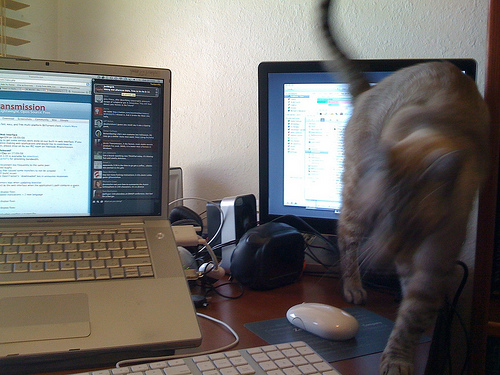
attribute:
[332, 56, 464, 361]
cat — gray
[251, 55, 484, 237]
flat screen — black, rectangular, computer monitor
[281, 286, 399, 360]
mouse — white, wireless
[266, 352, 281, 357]
key — white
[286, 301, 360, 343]
computer mouse — white, plastic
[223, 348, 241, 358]
key — white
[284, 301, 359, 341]
mouse — white, wireless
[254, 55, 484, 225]
computer monitor — additional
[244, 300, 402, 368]
mouse pad — Black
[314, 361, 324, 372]
key — white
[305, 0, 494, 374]
cat — brown, black, gray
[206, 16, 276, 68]
wall — white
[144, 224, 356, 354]
desk — wooden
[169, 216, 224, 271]
cable — white, plastic, connector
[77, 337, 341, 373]
keyboard — external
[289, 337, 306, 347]
key — white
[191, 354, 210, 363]
key — white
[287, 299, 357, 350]
mouse pad — square, flat, black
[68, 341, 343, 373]
keyboard — flat white, gray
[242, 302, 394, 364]
mousepad — black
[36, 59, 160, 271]
computer — equipment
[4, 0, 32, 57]
blinds — light beige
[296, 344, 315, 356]
key — white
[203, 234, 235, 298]
wires — messy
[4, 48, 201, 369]
laptop — gray, computer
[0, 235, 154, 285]
keyboard — built in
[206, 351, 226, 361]
key — white 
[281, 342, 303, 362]
key — white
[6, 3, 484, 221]
wall — white, bumpy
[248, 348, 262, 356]
key — white